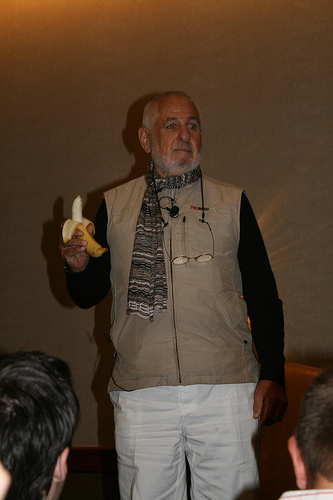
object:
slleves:
[235, 188, 289, 387]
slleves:
[63, 194, 111, 308]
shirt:
[62, 176, 281, 393]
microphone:
[158, 196, 180, 218]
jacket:
[102, 176, 260, 395]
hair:
[142, 98, 158, 127]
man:
[61, 90, 290, 499]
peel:
[63, 219, 107, 257]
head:
[0, 352, 80, 500]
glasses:
[163, 219, 216, 265]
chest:
[115, 207, 231, 268]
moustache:
[170, 143, 195, 153]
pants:
[108, 381, 261, 500]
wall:
[0, 1, 331, 444]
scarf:
[126, 164, 201, 318]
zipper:
[168, 191, 183, 386]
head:
[287, 362, 333, 499]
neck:
[152, 164, 199, 186]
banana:
[61, 194, 107, 258]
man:
[278, 367, 333, 499]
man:
[0, 348, 79, 499]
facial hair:
[147, 133, 203, 175]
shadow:
[41, 90, 161, 499]